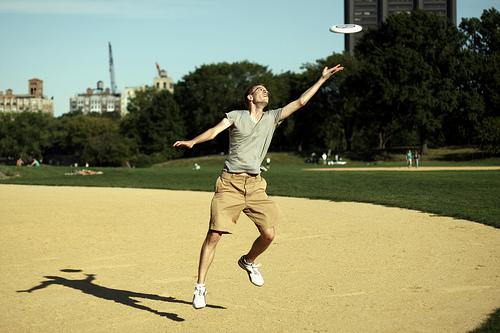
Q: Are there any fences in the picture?
A: No, there are no fences.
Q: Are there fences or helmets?
A: No, there are no fences or helmets.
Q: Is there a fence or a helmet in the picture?
A: No, there are no fences or helmets.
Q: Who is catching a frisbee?
A: The man is catching a frisbee.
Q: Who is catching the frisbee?
A: The man is catching a frisbee.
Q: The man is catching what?
A: The man is catching a frisbee.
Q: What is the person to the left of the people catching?
A: The man is catching a frisbee.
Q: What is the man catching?
A: The man is catching a frisbee.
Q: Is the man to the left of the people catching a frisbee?
A: Yes, the man is catching a frisbee.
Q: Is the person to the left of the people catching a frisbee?
A: Yes, the man is catching a frisbee.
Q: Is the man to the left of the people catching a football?
A: No, the man is catching a frisbee.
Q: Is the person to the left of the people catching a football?
A: No, the man is catching a frisbee.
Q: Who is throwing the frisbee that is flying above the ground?
A: The man is throwing the frisbee.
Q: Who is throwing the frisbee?
A: The man is throwing the frisbee.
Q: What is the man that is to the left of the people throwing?
A: The man is throwing the frisbee.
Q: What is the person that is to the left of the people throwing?
A: The man is throwing the frisbee.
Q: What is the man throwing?
A: The man is throwing the frisbee.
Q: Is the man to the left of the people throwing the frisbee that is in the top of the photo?
A: Yes, the man is throwing the frisbee.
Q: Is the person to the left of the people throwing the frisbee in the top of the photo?
A: Yes, the man is throwing the frisbee.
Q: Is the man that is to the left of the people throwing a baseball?
A: No, the man is throwing the frisbee.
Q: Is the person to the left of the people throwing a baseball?
A: No, the man is throwing the frisbee.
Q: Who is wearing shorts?
A: The man is wearing shorts.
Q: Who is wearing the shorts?
A: The man is wearing shorts.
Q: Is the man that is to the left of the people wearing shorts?
A: Yes, the man is wearing shorts.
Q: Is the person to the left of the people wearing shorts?
A: Yes, the man is wearing shorts.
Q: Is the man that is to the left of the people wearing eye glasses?
A: No, the man is wearing shorts.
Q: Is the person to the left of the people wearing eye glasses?
A: No, the man is wearing shorts.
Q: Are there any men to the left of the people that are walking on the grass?
A: Yes, there is a man to the left of the people.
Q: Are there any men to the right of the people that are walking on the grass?
A: No, the man is to the left of the people.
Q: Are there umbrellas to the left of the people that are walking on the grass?
A: No, there is a man to the left of the people.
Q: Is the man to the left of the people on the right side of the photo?
A: Yes, the man is to the left of the people.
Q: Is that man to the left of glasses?
A: No, the man is to the left of the people.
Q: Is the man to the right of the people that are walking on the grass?
A: No, the man is to the left of the people.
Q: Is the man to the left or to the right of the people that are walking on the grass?
A: The man is to the left of the people.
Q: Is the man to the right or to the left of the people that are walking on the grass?
A: The man is to the left of the people.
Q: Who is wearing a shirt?
A: The man is wearing a shirt.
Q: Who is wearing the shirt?
A: The man is wearing a shirt.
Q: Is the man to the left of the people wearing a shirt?
A: Yes, the man is wearing a shirt.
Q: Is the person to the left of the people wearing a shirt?
A: Yes, the man is wearing a shirt.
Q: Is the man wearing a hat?
A: No, the man is wearing a shirt.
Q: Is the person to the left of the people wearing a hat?
A: No, the man is wearing a shirt.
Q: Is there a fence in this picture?
A: No, there are no fences.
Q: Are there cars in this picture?
A: No, there are no cars.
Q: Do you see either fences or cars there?
A: No, there are no cars or fences.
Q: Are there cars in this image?
A: No, there are no cars.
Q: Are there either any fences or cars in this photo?
A: No, there are no cars or fences.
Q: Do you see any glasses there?
A: No, there are no glasses.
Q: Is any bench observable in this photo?
A: No, there are no benches.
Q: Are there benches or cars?
A: No, there are no benches or cars.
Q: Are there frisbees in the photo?
A: Yes, there is a frisbee.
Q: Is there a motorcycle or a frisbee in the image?
A: Yes, there is a frisbee.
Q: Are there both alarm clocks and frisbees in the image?
A: No, there is a frisbee but no alarm clocks.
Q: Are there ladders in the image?
A: No, there are no ladders.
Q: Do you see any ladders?
A: No, there are no ladders.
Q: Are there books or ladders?
A: No, there are no ladders or books.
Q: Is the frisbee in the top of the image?
A: Yes, the frisbee is in the top of the image.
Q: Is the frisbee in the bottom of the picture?
A: No, the frisbee is in the top of the image.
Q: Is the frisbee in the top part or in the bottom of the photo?
A: The frisbee is in the top of the image.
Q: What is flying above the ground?
A: The frisbee is flying above the ground.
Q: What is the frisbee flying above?
A: The frisbee is flying above the ground.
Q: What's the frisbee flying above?
A: The frisbee is flying above the ground.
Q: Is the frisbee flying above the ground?
A: Yes, the frisbee is flying above the ground.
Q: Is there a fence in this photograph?
A: No, there are no fences.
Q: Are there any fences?
A: No, there are no fences.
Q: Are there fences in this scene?
A: No, there are no fences.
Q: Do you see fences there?
A: No, there are no fences.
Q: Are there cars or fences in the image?
A: No, there are no fences or cars.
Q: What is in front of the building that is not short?
A: The trees are in front of the building.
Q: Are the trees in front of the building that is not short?
A: Yes, the trees are in front of the building.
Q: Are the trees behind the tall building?
A: No, the trees are in front of the building.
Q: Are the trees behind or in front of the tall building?
A: The trees are in front of the building.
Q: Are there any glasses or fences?
A: No, there are no fences or glasses.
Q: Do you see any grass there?
A: Yes, there is grass.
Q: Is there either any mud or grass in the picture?
A: Yes, there is grass.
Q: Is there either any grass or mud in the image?
A: Yes, there is grass.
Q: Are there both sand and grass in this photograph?
A: Yes, there are both grass and sand.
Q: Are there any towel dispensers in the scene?
A: No, there are no towel dispensers.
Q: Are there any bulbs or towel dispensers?
A: No, there are no towel dispensers or bulbs.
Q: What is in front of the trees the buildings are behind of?
A: The grass is in front of the trees.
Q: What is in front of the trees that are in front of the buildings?
A: The grass is in front of the trees.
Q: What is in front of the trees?
A: The grass is in front of the trees.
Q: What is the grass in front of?
A: The grass is in front of the trees.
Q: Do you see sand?
A: Yes, there is sand.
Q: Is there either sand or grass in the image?
A: Yes, there is sand.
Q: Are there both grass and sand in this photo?
A: Yes, there are both sand and grass.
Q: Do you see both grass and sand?
A: Yes, there are both sand and grass.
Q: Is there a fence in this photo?
A: No, there are no fences.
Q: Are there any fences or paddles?
A: No, there are no fences or paddles.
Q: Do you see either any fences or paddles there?
A: No, there are no fences or paddles.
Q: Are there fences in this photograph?
A: No, there are no fences.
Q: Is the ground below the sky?
A: Yes, the ground is below the sky.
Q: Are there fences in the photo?
A: No, there are no fences.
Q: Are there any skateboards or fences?
A: No, there are no fences or skateboards.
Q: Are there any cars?
A: No, there are no cars.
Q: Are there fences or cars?
A: No, there are no cars or fences.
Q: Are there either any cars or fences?
A: No, there are no cars or fences.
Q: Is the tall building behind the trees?
A: Yes, the building is behind the trees.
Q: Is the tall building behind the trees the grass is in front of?
A: Yes, the building is behind the trees.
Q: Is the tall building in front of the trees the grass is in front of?
A: No, the building is behind the trees.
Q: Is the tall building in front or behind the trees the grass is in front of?
A: The building is behind the trees.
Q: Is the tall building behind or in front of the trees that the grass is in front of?
A: The building is behind the trees.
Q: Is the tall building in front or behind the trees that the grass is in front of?
A: The building is behind the trees.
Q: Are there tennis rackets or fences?
A: No, there are no fences or tennis rackets.